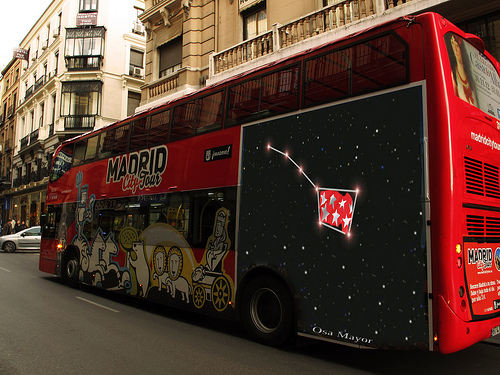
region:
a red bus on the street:
[37, 15, 494, 374]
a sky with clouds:
[2, 1, 52, 73]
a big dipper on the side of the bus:
[255, 129, 379, 249]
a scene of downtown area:
[1, 0, 498, 370]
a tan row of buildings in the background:
[10, 11, 451, 256]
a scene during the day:
[13, 19, 498, 352]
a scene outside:
[10, 10, 489, 319]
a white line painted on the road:
[59, 280, 118, 334]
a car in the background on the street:
[0, 227, 56, 262]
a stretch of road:
[1, 240, 353, 372]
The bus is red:
[36, 8, 498, 359]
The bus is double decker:
[36, 7, 498, 358]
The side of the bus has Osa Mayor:
[238, 78, 433, 362]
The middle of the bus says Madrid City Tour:
[106, 143, 173, 193]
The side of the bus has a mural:
[57, 171, 237, 316]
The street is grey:
[1, 250, 499, 374]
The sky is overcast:
[0, 1, 53, 71]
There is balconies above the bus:
[133, 2, 498, 114]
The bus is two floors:
[38, 61, 499, 356]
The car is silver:
[1, 214, 42, 256]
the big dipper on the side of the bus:
[241, 128, 421, 337]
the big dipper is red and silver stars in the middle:
[263, 140, 378, 250]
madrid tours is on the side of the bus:
[103, 141, 176, 190]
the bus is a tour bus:
[42, 47, 489, 364]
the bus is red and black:
[36, 49, 499, 356]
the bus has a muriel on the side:
[56, 187, 243, 320]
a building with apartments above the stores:
[16, 35, 138, 232]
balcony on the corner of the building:
[61, 74, 105, 135]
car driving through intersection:
[2, 223, 37, 255]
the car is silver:
[1, 223, 40, 259]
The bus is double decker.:
[40, 8, 498, 364]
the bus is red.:
[39, 22, 495, 352]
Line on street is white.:
[67, 283, 122, 318]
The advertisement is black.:
[231, 75, 433, 360]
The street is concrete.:
[0, 242, 323, 372]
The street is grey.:
[2, 247, 332, 372]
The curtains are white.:
[62, 26, 104, 71]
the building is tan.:
[14, 2, 149, 153]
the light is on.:
[50, 236, 65, 253]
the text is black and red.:
[102, 143, 170, 195]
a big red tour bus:
[37, 15, 496, 360]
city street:
[4, 246, 395, 373]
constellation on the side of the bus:
[257, 136, 371, 253]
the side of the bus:
[40, 23, 454, 355]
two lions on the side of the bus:
[147, 243, 200, 308]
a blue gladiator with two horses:
[62, 169, 124, 290]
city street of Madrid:
[10, 11, 490, 358]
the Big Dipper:
[257, 136, 367, 244]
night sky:
[245, 99, 430, 334]